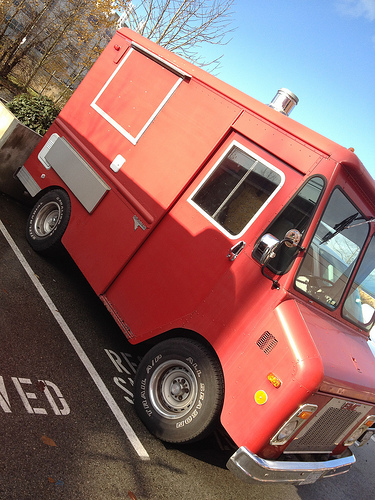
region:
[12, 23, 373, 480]
a red car on the road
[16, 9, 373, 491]
red truck is closed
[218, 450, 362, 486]
bumper of truck si metal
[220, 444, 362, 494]
bumper is color silver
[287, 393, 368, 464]
a vent in front of old truck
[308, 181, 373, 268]
a wipe over windshield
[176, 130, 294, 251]
frame of window is white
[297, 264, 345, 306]
a steering wheel inside the truck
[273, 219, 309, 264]
a mirror on side a truck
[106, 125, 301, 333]
door of truck has a window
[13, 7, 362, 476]
large red truck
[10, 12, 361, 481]
large red truck parked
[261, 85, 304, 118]
spout on top of truck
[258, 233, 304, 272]
side view mirror of truck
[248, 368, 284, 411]
side safety lights on truck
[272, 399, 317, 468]
front lights on truck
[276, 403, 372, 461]
front grill on truck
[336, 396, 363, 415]
logo on front of grill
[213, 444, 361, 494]
silver bumper on truck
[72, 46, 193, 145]
square opening area on side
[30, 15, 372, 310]
a red truck with white trim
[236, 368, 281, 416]
yellow reflector on side of vehicle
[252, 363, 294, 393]
orange signal light on side of vehicle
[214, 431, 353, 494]
the vehicle's front bumper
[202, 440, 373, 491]
the front bumper is chrome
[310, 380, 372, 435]
a GMC logo on the vehicle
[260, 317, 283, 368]
a square of holes on the vehicle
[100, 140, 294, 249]
vehicle's side window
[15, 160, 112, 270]
black tire with white writing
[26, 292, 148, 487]
reserved parking spaces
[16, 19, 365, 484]
slanted red truck on paved parking lot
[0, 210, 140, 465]
white line and writing on ground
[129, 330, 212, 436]
lettering in a circle around tire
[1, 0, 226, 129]
trees and building behind truck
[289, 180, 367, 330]
two glass panels in front of truck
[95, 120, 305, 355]
door with glass panels and handle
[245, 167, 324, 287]
triangular panel on side of truck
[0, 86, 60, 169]
planter with green plant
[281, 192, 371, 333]
car showing through truck windows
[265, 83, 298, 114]
shiny silver knob on roof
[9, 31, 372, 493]
van parked in reserved parking space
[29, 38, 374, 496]
parked red panel truck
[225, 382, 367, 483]
front grill of truck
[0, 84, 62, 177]
concrete planter by parking lot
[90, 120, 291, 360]
passenger side door of truck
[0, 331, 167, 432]
writing on parking lot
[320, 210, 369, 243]
windshield wiper on van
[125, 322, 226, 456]
truck tire parked in lot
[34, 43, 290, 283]
red orange van with white trim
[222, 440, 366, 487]
front bumper of van